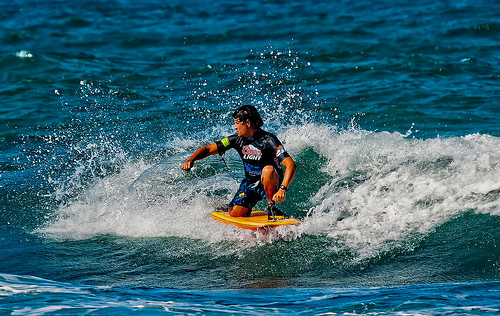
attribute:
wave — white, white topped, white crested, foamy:
[10, 123, 499, 271]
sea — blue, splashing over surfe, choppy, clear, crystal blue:
[3, 1, 497, 310]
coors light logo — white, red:
[241, 142, 265, 164]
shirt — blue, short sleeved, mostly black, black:
[212, 130, 288, 183]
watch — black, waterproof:
[277, 184, 288, 191]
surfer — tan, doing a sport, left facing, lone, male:
[175, 103, 300, 219]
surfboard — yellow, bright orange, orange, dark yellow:
[210, 203, 298, 235]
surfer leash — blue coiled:
[221, 156, 274, 206]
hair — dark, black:
[231, 103, 262, 131]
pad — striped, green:
[221, 135, 231, 147]